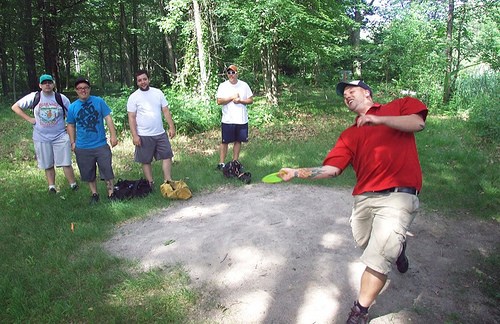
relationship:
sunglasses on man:
[226, 69, 237, 77] [213, 62, 255, 169]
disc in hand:
[259, 170, 285, 187] [277, 166, 293, 183]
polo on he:
[322, 97, 427, 195] [275, 81, 425, 324]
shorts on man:
[317, 177, 425, 273] [284, 35, 458, 322]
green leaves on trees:
[0, 2, 498, 64] [2, 0, 497, 111]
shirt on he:
[14, 95, 79, 136] [67, 78, 118, 204]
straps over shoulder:
[29, 92, 66, 108] [26, 88, 67, 105]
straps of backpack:
[29, 92, 66, 108] [108, 159, 171, 235]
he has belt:
[275, 81, 425, 324] [375, 187, 421, 199]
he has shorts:
[275, 81, 425, 324] [349, 186, 419, 276]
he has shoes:
[275, 81, 425, 324] [343, 236, 410, 322]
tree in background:
[157, 2, 225, 118] [10, 6, 499, 208]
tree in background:
[368, 9, 443, 94] [10, 6, 499, 208]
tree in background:
[433, 0, 489, 112] [10, 6, 499, 208]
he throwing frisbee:
[275, 81, 425, 324] [260, 170, 284, 185]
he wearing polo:
[275, 81, 425, 324] [325, 97, 428, 193]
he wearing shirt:
[67, 78, 118, 204] [66, 96, 112, 150]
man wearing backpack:
[17, 70, 81, 198] [28, 87, 67, 114]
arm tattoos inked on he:
[290, 167, 331, 181] [275, 81, 425, 324]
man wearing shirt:
[125, 68, 177, 190] [216, 79, 253, 125]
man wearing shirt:
[213, 62, 255, 169] [127, 87, 169, 137]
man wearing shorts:
[125, 68, 177, 190] [131, 131, 174, 164]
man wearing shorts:
[213, 62, 255, 169] [218, 116, 250, 144]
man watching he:
[213, 62, 255, 169] [275, 81, 425, 324]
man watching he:
[125, 68, 177, 190] [275, 81, 425, 324]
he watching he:
[67, 78, 118, 204] [275, 81, 425, 324]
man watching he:
[11, 74, 79, 195] [275, 81, 425, 324]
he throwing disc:
[275, 81, 425, 324] [262, 171, 285, 182]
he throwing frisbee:
[275, 81, 425, 324] [259, 160, 290, 191]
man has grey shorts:
[125, 68, 177, 190] [132, 131, 173, 163]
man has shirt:
[125, 68, 177, 190] [127, 87, 169, 137]